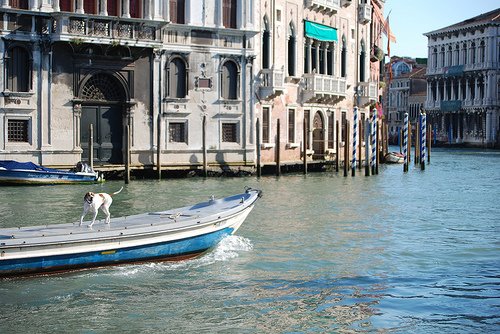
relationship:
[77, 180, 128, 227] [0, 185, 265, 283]
dog on boat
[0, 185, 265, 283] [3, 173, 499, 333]
boat in water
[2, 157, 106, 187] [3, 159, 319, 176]
boat on dock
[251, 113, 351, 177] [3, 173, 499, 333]
poles in water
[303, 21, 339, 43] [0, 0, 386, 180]
awning on building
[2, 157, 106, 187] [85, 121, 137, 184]
boat between poles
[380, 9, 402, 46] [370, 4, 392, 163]
flag side of building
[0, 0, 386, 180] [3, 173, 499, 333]
building on water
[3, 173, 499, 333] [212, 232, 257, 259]
water has wave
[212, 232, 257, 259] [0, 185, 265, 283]
wave in front boat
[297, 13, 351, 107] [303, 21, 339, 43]
balcony has curtain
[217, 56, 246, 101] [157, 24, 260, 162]
window on wall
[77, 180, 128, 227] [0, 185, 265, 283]
dog on a boat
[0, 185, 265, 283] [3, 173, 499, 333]
boat floating o river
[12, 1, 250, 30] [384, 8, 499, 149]
windows of building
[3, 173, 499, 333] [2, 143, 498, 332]
water of canal